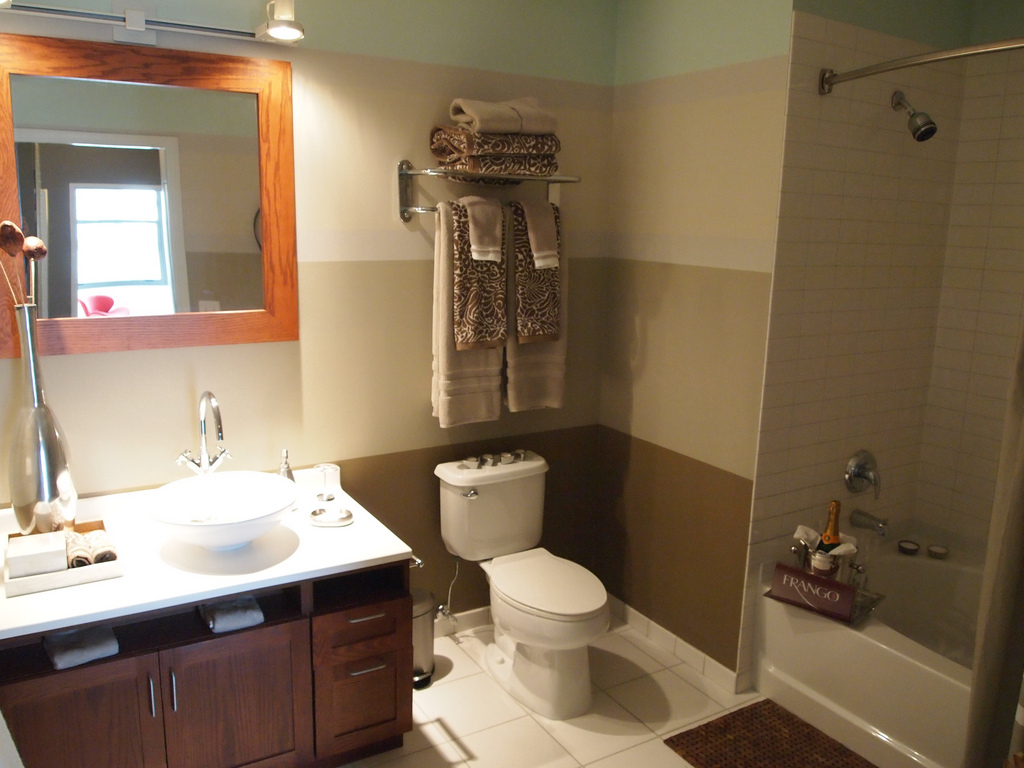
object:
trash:
[408, 588, 435, 683]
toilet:
[435, 451, 610, 720]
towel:
[449, 99, 555, 134]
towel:
[429, 125, 560, 156]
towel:
[441, 154, 558, 176]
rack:
[399, 160, 582, 221]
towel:
[41, 623, 120, 670]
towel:
[197, 593, 265, 633]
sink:
[150, 470, 301, 552]